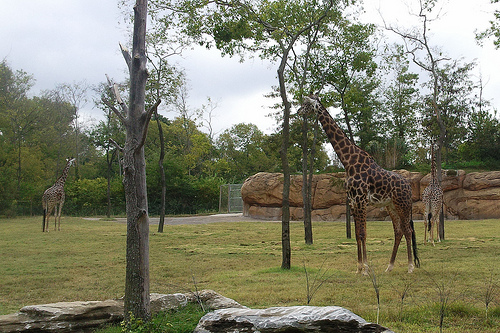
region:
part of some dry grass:
[186, 234, 254, 269]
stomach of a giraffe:
[363, 176, 393, 209]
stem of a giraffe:
[113, 227, 163, 298]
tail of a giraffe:
[411, 235, 421, 264]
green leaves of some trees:
[162, 164, 216, 206]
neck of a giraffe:
[321, 122, 343, 152]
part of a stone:
[266, 307, 305, 320]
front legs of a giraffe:
[339, 222, 373, 262]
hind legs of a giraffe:
[403, 251, 416, 263]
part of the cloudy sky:
[212, 65, 252, 114]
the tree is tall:
[216, 7, 351, 275]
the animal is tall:
[290, 72, 435, 284]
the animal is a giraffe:
[295, 65, 432, 282]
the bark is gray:
[105, 18, 195, 328]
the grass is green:
[185, 233, 265, 281]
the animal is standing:
[296, 77, 435, 297]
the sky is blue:
[5, 9, 108, 64]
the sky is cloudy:
[30, 9, 297, 144]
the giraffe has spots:
[301, 87, 436, 226]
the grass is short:
[200, 229, 295, 284]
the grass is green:
[222, 187, 330, 287]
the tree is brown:
[94, 30, 171, 317]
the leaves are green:
[203, 10, 328, 48]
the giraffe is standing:
[299, 60, 436, 287]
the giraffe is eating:
[283, 58, 430, 288]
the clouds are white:
[17, 5, 112, 69]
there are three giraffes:
[25, 86, 460, 288]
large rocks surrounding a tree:
[6, 279, 379, 329]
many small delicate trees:
[85, 3, 483, 286]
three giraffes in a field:
[22, 91, 459, 291]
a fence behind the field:
[216, 174, 250, 220]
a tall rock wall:
[229, 146, 498, 228]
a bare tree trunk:
[108, 0, 176, 325]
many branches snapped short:
[80, 21, 191, 228]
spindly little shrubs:
[284, 246, 499, 328]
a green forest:
[0, 50, 346, 236]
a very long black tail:
[388, 167, 432, 284]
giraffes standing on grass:
[33, 55, 463, 285]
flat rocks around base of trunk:
[31, 276, 336, 321]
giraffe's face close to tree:
[265, 70, 420, 285]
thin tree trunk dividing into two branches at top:
[220, 11, 305, 271]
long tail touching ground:
[386, 155, 426, 275]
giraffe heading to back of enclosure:
[12, 140, 102, 255]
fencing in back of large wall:
[197, 165, 262, 232]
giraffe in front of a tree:
[420, 105, 450, 251]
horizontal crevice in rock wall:
[231, 190, 343, 220]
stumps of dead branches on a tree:
[91, 38, 163, 240]